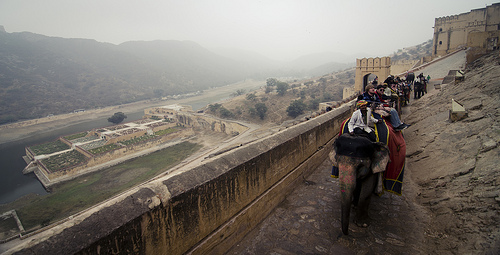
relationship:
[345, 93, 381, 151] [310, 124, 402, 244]
person riding elephant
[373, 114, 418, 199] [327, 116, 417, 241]
cloth over elephant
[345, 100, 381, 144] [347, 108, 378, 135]
person wearing jacket